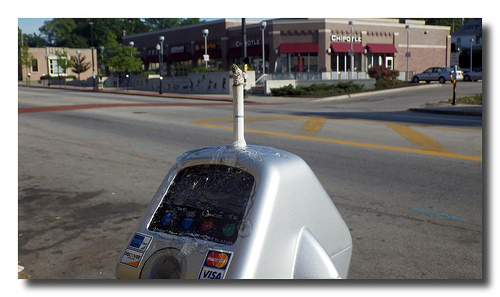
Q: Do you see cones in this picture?
A: No, there are no cones.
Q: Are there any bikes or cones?
A: No, there are no cones or bikes.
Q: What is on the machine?
A: The logo is on the machine.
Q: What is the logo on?
A: The logo is on the machine.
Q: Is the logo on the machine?
A: Yes, the logo is on the machine.